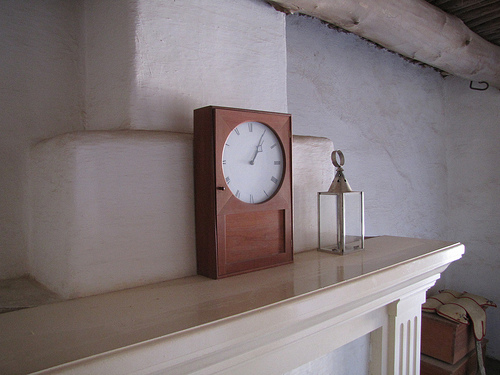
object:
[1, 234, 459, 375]
mantle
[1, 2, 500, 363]
wall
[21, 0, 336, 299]
chimney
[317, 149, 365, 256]
metal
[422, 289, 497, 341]
boes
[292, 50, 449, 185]
ground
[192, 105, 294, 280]
clock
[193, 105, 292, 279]
frame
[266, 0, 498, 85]
log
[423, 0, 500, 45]
roof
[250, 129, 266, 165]
handles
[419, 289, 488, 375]
box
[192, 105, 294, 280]
wooden cabinet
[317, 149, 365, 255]
decoration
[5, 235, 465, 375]
fireplace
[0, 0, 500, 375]
house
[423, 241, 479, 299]
corner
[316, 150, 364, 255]
thing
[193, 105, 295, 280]
cabinet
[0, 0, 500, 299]
building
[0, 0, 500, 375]
photo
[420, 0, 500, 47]
ceiling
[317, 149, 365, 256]
box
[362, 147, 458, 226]
concrete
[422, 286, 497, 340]
mats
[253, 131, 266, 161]
clock arm